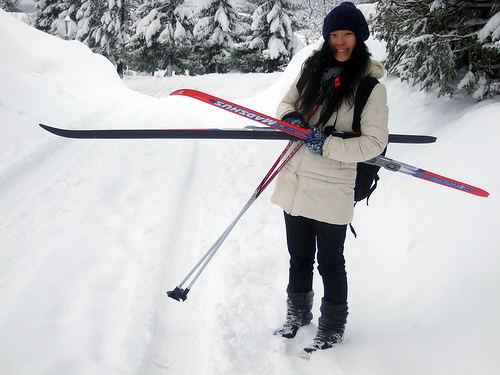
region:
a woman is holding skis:
[37, 2, 491, 352]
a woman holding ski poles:
[160, 107, 336, 301]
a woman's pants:
[272, 212, 349, 364]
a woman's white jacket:
[272, 59, 390, 223]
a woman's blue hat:
[322, 2, 367, 41]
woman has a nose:
[333, 36, 346, 45]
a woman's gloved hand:
[305, 124, 325, 155]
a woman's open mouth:
[335, 47, 348, 54]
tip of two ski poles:
[167, 287, 188, 299]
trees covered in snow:
[35, 0, 293, 78]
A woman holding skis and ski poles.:
[39, 0, 490, 358]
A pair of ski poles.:
[165, 74, 341, 301]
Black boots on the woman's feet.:
[273, 286, 348, 355]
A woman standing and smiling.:
[275, 1, 388, 354]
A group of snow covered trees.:
[35, 0, 305, 77]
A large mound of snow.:
[0, 7, 155, 113]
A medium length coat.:
[269, 59, 389, 225]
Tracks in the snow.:
[1, 101, 215, 373]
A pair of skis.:
[35, 87, 488, 203]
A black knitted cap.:
[321, 1, 369, 39]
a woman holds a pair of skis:
[35, 2, 492, 357]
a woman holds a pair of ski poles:
[147, 3, 398, 361]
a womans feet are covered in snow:
[262, 3, 394, 360]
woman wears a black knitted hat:
[272, 1, 390, 365]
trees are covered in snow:
[34, 1, 300, 76]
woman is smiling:
[272, 4, 394, 363]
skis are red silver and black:
[34, 83, 491, 201]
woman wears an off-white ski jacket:
[268, 0, 390, 365]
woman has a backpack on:
[264, 1, 391, 361]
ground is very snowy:
[4, 13, 498, 373]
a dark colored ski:
[39, 124, 443, 143]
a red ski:
[169, 88, 489, 197]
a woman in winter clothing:
[269, 4, 389, 359]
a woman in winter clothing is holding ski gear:
[41, 4, 498, 356]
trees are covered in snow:
[37, 0, 294, 82]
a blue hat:
[322, 2, 370, 42]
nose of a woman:
[336, 37, 346, 48]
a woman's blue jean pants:
[277, 210, 347, 359]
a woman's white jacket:
[277, 54, 389, 228]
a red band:
[332, 77, 340, 88]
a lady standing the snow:
[259, 5, 404, 371]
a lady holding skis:
[93, 6, 475, 352]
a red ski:
[171, 79, 489, 207]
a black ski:
[41, 119, 434, 153]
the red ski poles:
[198, 137, 294, 301]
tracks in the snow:
[26, 141, 179, 322]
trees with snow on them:
[48, 13, 293, 60]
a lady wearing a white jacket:
[276, 20, 381, 322]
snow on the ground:
[213, 325, 383, 361]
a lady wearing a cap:
[302, 5, 384, 140]